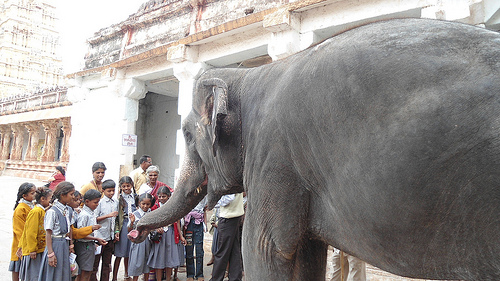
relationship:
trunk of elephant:
[137, 130, 218, 239] [153, 27, 465, 265]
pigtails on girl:
[14, 185, 29, 207] [109, 168, 141, 201]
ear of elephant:
[201, 73, 265, 178] [153, 27, 465, 265]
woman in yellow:
[139, 156, 172, 180] [24, 206, 64, 226]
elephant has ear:
[153, 27, 465, 265] [201, 73, 265, 178]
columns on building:
[8, 86, 71, 166] [61, 19, 292, 157]